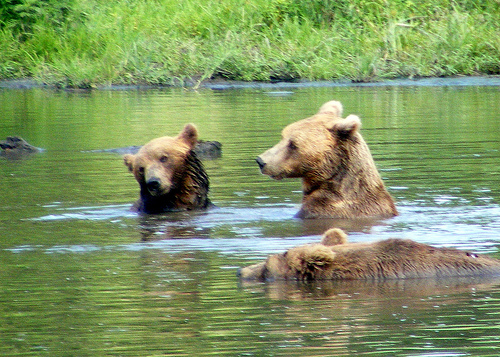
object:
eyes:
[138, 167, 144, 175]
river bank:
[0, 69, 500, 89]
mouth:
[254, 156, 283, 180]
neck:
[134, 171, 208, 209]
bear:
[254, 100, 399, 219]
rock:
[96, 139, 223, 159]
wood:
[79, 139, 224, 158]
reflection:
[135, 218, 202, 333]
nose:
[146, 180, 161, 193]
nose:
[256, 157, 266, 169]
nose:
[235, 269, 242, 278]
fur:
[133, 153, 210, 211]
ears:
[320, 101, 342, 118]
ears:
[328, 112, 362, 134]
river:
[0, 74, 500, 357]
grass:
[0, 0, 500, 89]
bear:
[120, 122, 209, 211]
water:
[0, 83, 498, 357]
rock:
[0, 136, 38, 157]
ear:
[179, 123, 198, 146]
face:
[134, 137, 180, 193]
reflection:
[254, 275, 500, 357]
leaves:
[0, 0, 85, 44]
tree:
[3, 1, 99, 83]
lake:
[0, 75, 500, 357]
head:
[237, 227, 348, 283]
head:
[123, 123, 199, 197]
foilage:
[0, 0, 500, 82]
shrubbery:
[0, 0, 500, 87]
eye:
[160, 156, 168, 163]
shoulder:
[286, 180, 386, 220]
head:
[255, 100, 361, 182]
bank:
[0, 0, 499, 86]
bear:
[236, 226, 499, 282]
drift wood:
[1, 138, 223, 162]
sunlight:
[4, 188, 499, 261]